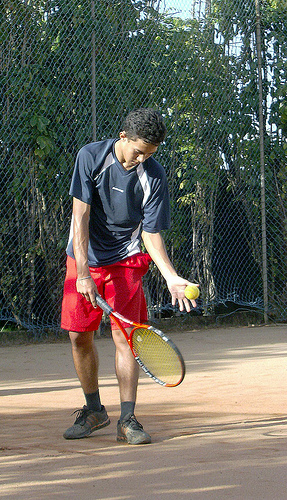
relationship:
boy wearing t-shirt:
[59, 107, 200, 445] [66, 136, 170, 268]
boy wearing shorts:
[59, 107, 200, 445] [60, 251, 151, 330]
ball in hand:
[184, 285, 200, 301] [166, 276, 201, 313]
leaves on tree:
[100, 14, 283, 310] [206, 1, 279, 308]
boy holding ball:
[59, 107, 200, 445] [180, 274, 207, 307]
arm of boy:
[134, 213, 197, 306] [59, 107, 200, 445]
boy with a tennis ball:
[59, 107, 200, 445] [184, 286, 202, 300]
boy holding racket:
[59, 107, 200, 445] [93, 291, 190, 388]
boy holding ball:
[59, 107, 200, 445] [184, 285, 200, 301]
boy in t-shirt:
[59, 107, 200, 445] [66, 136, 170, 268]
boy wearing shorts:
[59, 107, 200, 445] [49, 219, 174, 349]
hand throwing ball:
[165, 276, 201, 312] [183, 283, 201, 300]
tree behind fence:
[13, 4, 280, 326] [1, 1, 286, 324]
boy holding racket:
[59, 107, 200, 445] [72, 268, 204, 396]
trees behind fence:
[1, 0, 92, 238] [1, 1, 286, 324]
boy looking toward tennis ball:
[59, 107, 200, 445] [185, 285, 200, 298]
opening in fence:
[5, 302, 269, 341] [1, 1, 286, 324]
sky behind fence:
[3, 1, 284, 168] [1, 1, 286, 324]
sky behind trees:
[3, 1, 284, 168] [0, 1, 284, 329]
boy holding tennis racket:
[59, 107, 200, 445] [94, 290, 184, 387]